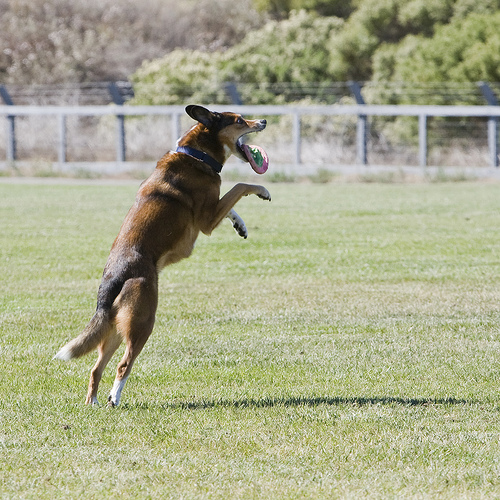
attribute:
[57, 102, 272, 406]
dog — black, brown, white, jumping, playing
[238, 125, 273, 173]
mouth — wide open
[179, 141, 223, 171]
collar — blue, navy blue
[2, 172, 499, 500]
grass — large, open, green, brown, growing, short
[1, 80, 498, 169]
fence — barbed wire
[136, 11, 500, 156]
trees — green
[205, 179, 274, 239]
front legs — airborne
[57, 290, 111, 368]
tail — furry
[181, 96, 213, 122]
ears — popped up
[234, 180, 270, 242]
paws — white